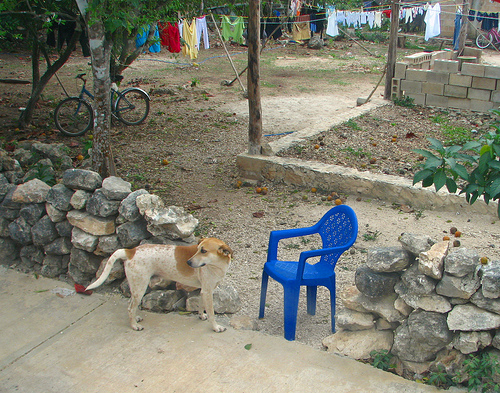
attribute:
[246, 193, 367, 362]
chair —  blue,   plastic 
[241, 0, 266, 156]
wood pole —   cement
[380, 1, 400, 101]
wood pole —   cement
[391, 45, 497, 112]
cinder blocks —  stacked up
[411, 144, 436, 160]
leaf —  Green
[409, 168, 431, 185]
leaf —  Green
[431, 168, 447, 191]
leaf —  Green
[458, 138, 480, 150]
leaf —  Green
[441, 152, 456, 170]
leaf —  Green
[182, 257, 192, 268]
nose —  black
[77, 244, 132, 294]
tail —  White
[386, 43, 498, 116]
blocks —  cement,  stacked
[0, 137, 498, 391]
walls — rock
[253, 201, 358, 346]
chair — blue,   blue,  plastic, bright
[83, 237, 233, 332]
dog —  white and brown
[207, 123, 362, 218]
curbing — concrete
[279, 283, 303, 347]
leg —  chair's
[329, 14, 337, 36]
clothes — drying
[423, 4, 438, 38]
clothes — drying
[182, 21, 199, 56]
clothes — drying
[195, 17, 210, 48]
clothes — drying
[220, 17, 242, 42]
clothes — drying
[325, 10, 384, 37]
white clothes —  white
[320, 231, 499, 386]
wall — stone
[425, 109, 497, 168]
leaves — green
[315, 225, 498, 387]
stones —  stacked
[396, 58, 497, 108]
blocks —  Large,  cement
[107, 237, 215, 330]
dog — brown, white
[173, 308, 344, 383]
cement — poured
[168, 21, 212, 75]
garment —  clothing ,  yellow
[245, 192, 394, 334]
chair —  blue,  plastic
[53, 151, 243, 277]
rocks —  Large,  gray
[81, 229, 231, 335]
dog —  brown and white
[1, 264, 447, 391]
patio — cement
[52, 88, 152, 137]
wheels —  two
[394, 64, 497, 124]
wall —  stone